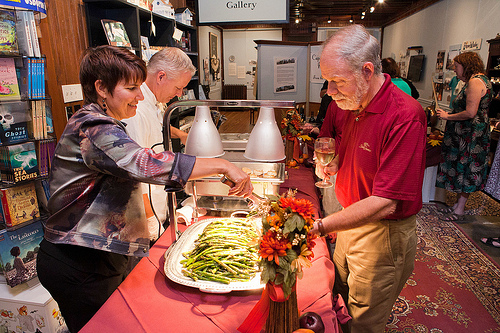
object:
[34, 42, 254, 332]
person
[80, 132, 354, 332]
table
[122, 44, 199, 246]
person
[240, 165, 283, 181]
buffet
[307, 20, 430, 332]
man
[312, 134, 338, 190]
wine glass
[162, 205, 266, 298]
plate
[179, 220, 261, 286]
food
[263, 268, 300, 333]
vase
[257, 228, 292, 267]
flowers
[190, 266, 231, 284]
asparagus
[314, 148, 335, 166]
white wine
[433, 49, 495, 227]
woman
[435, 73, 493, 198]
dress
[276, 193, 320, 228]
flower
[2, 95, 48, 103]
rack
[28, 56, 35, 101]
book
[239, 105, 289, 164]
lamp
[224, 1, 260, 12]
gallery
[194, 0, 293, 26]
sign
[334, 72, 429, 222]
shirt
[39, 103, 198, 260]
jacket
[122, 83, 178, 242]
shirt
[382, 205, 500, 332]
carpet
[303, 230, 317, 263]
flower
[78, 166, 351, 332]
table cloth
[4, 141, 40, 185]
book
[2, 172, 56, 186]
shelf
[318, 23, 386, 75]
hair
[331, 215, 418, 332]
pants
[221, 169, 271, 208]
tongs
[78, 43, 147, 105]
hair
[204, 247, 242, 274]
asparagus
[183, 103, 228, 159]
lamp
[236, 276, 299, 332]
bow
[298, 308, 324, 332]
apple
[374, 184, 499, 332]
floor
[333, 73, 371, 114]
beard